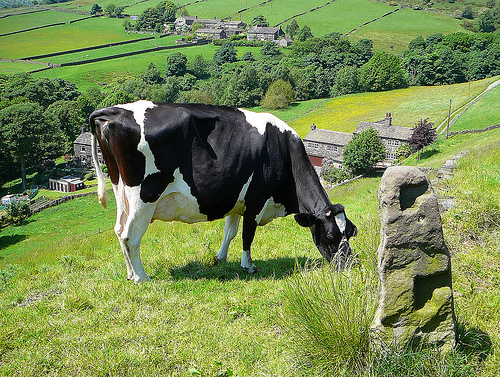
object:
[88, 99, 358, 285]
cow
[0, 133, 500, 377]
hill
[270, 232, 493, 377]
grass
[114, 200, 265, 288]
legs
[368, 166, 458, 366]
pillar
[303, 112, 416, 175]
building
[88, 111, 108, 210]
tail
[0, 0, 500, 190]
trees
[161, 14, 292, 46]
group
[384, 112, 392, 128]
chimney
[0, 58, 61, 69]
fence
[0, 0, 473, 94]
field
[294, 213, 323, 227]
ear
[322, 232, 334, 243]
eye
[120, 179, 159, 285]
leg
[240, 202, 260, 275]
leg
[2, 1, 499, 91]
distance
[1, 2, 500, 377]
country side